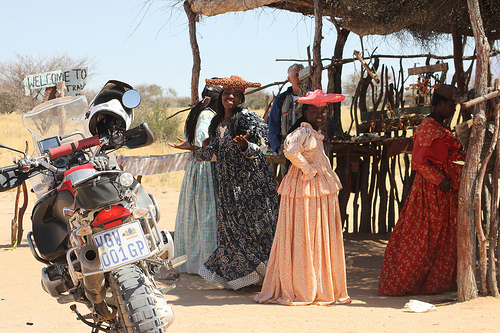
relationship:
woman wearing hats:
[253, 89, 350, 305] [203, 72, 346, 104]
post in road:
[55, 78, 67, 137] [2, 170, 499, 331]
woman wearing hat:
[253, 89, 350, 305] [293, 85, 340, 111]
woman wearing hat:
[253, 89, 350, 305] [286, 81, 358, 116]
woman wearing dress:
[168, 75, 277, 290] [198, 109, 277, 293]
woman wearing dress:
[253, 89, 350, 305] [252, 123, 349, 305]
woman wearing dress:
[375, 84, 464, 297] [385, 117, 460, 297]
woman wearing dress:
[375, 84, 464, 297] [374, 130, 466, 272]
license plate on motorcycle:
[90, 217, 152, 272] [2, 94, 190, 331]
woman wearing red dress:
[375, 84, 464, 297] [356, 89, 482, 306]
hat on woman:
[206, 74, 262, 90] [375, 84, 464, 297]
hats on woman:
[298, 89, 346, 107] [253, 89, 350, 305]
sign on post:
[20, 60, 90, 97] [22, 65, 87, 137]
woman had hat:
[253, 89, 350, 305] [294, 86, 341, 106]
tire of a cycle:
[105, 255, 169, 332] [0, 79, 186, 330]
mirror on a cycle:
[123, 89, 139, 107] [0, 132, 174, 332]